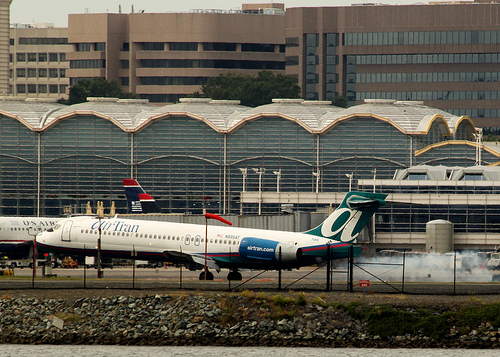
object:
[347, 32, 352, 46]
window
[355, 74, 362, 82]
window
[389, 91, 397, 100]
window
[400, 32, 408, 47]
window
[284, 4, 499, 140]
building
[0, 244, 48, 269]
cart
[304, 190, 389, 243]
airplane terminal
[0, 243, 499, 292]
fence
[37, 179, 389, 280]
airplane